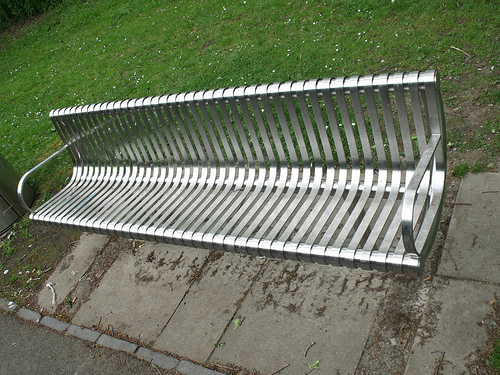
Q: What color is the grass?
A: Green.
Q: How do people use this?
A: For sitting.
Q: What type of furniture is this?
A: A bench.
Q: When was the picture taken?
A: Daytime.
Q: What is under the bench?
A: Concrete squares.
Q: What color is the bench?
A: Silver.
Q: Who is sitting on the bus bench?
A: Nobody.